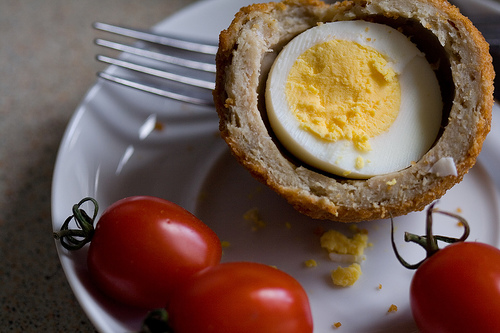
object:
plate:
[49, 0, 500, 333]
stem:
[388, 200, 470, 270]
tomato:
[58, 196, 500, 331]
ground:
[416, 147, 465, 183]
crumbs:
[220, 208, 369, 288]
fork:
[91, 21, 217, 108]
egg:
[265, 19, 442, 179]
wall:
[223, 95, 251, 141]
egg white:
[265, 19, 458, 176]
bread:
[212, 0, 497, 224]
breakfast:
[50, 0, 500, 333]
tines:
[97, 71, 215, 107]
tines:
[93, 38, 216, 74]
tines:
[92, 21, 220, 55]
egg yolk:
[284, 38, 401, 170]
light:
[156, 220, 208, 265]